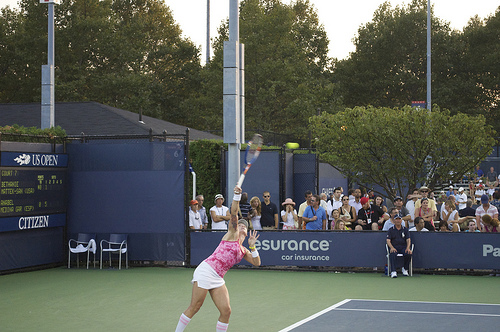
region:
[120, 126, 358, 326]
A person playing tennis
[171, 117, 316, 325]
A woman playing tennis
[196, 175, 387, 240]
people watching a person playing tennis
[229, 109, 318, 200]
A tennis racket and ball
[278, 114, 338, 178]
A green tennis ball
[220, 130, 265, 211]
A hand holding a tennis racket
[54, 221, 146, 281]
Two chairs on a tennis court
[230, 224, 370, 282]
An "esurance" sponsor sign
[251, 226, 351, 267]
White letters on a blue background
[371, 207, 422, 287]
A person in a chair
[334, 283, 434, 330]
the tennis court is blue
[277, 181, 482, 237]
fans watching the tennis match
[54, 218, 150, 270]
two chairs on the tennis court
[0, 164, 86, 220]
tennis court scoreboard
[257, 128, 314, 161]
tennis ball is yellow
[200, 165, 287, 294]
tennis player has on pick shirt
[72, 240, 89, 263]
white towel sitting on chair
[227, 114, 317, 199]
hitting the tennis ball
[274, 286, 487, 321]
white lines on the tennis court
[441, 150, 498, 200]
stands for the fans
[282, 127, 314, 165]
Fluorescent green tennis ball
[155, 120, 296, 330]
Lady hitting a tennis ball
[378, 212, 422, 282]
Person sitting in a chair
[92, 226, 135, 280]
Metal and plastic chair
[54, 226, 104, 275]
Metal and plastic chair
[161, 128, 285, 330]
Person wearing white shorts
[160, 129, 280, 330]
Person wearing a pink shirt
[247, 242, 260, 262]
White cloth wrist band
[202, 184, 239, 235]
Person wearing white shirt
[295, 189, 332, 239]
Person wearing blue shirt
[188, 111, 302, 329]
woman playing tennis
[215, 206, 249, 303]
woman in a pink tennis shirt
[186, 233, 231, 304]
white tennis skirt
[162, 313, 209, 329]
white and pink knee high sock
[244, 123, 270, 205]
tennis racket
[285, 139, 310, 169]
yellow tennis ball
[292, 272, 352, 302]
the green on the tennis court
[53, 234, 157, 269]
two white chairs on tennis court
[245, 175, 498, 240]
people in the audience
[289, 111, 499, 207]
tree behind the audience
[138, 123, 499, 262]
Crowd of people watching a tennis match.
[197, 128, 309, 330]
Tennis playing serving the ball.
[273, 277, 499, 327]
Blue tennis court with white lines.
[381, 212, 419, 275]
Line judge sitting in a chair.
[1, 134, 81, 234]
Electronic scoreboard with branding.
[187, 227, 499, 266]
Metal and plastic fence with advertisement.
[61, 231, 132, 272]
White chairs.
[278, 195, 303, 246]
Woman holding her hands to her face.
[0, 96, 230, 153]
Roof of a building with shingles.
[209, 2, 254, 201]
Tall metal light pole.